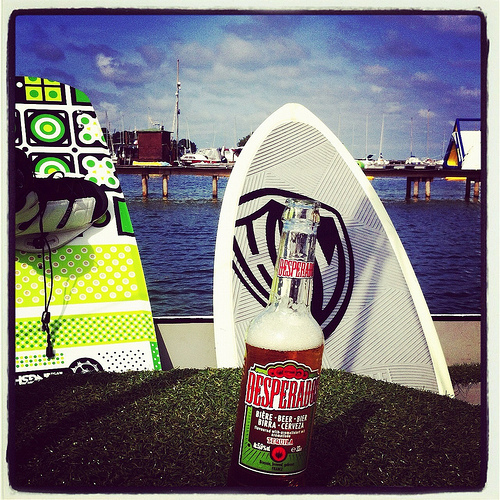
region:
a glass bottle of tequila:
[229, 193, 321, 494]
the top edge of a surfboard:
[212, 100, 455, 397]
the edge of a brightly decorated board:
[13, 73, 163, 379]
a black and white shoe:
[10, 145, 110, 237]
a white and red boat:
[177, 143, 238, 170]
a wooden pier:
[114, 163, 233, 203]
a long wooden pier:
[364, 164, 484, 204]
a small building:
[132, 128, 177, 166]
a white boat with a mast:
[362, 108, 397, 170]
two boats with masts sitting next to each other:
[404, 108, 444, 169]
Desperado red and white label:
[272, 254, 316, 284]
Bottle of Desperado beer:
[230, 191, 325, 489]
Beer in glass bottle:
[225, 309, 327, 487]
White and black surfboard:
[206, 93, 458, 425]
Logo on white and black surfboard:
[227, 185, 359, 346]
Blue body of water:
[120, 170, 484, 319]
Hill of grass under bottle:
[26, 359, 496, 496]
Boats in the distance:
[168, 127, 463, 177]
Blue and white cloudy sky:
[17, 18, 480, 157]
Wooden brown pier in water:
[109, 158, 483, 231]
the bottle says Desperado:
[241, 173, 338, 480]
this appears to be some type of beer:
[223, 189, 331, 480]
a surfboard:
[173, 103, 445, 414]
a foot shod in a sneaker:
[23, 148, 118, 258]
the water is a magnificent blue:
[154, 218, 201, 303]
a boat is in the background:
[181, 134, 236, 172]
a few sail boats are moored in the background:
[357, 105, 447, 175]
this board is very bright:
[25, 82, 120, 388]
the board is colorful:
[25, 101, 130, 352]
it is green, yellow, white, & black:
[36, 102, 155, 342]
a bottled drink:
[127, 138, 380, 490]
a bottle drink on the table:
[135, 158, 482, 499]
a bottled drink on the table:
[28, 162, 483, 496]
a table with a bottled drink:
[36, 116, 476, 493]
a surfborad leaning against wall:
[184, 53, 489, 473]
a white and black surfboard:
[207, 86, 458, 478]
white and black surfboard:
[175, 48, 496, 490]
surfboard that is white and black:
[182, 76, 446, 496]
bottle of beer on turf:
[216, 183, 345, 483]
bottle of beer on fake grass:
[247, 166, 346, 481]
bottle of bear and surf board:
[194, 88, 446, 446]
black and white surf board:
[216, 81, 455, 411]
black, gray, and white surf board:
[191, 78, 466, 496]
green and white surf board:
[13, 66, 174, 401]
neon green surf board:
[17, 66, 174, 397]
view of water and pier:
[112, 94, 452, 341]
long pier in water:
[121, 135, 472, 237]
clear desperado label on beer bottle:
[236, 331, 352, 446]